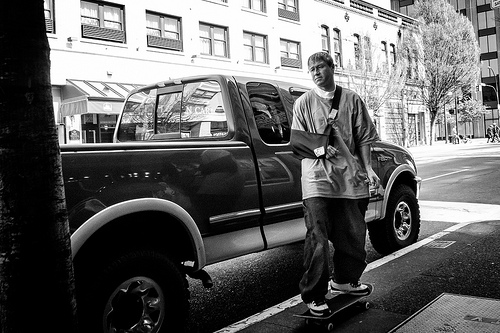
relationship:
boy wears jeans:
[286, 48, 378, 311] [297, 195, 371, 298]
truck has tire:
[68, 74, 425, 326] [367, 181, 425, 256]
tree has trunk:
[398, 0, 482, 141] [430, 136, 441, 156]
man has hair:
[286, 48, 378, 311] [310, 53, 337, 63]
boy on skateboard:
[286, 48, 378, 311] [288, 281, 377, 325]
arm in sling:
[291, 136, 342, 158] [279, 123, 338, 164]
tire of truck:
[367, 181, 425, 256] [68, 74, 425, 326]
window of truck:
[242, 81, 293, 143] [68, 74, 425, 326]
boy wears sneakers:
[286, 48, 378, 311] [288, 281, 377, 325]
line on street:
[424, 158, 487, 196] [424, 150, 495, 254]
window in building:
[138, 10, 200, 50] [54, 14, 432, 93]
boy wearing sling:
[286, 48, 378, 311] [279, 123, 338, 164]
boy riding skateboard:
[286, 48, 378, 311] [288, 281, 377, 325]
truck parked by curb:
[68, 74, 425, 326] [422, 224, 466, 248]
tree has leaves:
[398, 0, 482, 141] [441, 9, 468, 37]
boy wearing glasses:
[286, 48, 378, 311] [352, 10, 366, 16]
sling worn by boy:
[279, 123, 338, 164] [286, 48, 378, 311]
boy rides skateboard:
[286, 48, 378, 311] [288, 281, 377, 325]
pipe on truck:
[186, 261, 224, 286] [68, 74, 425, 326]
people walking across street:
[479, 120, 499, 139] [424, 150, 495, 254]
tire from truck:
[367, 181, 425, 256] [68, 74, 425, 326]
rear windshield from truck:
[121, 83, 224, 139] [68, 74, 425, 326]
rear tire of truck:
[86, 249, 193, 331] [68, 74, 425, 326]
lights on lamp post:
[472, 59, 496, 91] [475, 69, 500, 139]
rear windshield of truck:
[121, 83, 224, 139] [68, 74, 425, 326]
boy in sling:
[286, 48, 378, 311] [279, 123, 338, 164]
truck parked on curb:
[68, 74, 425, 326] [422, 224, 466, 248]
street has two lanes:
[424, 150, 495, 254] [424, 156, 499, 183]